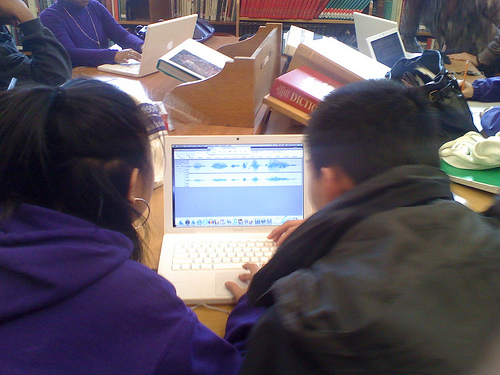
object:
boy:
[240, 77, 500, 374]